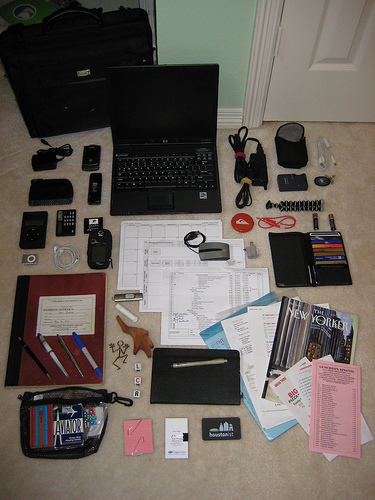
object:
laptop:
[102, 61, 223, 216]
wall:
[156, 0, 258, 131]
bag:
[0, 5, 161, 141]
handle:
[41, 4, 106, 29]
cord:
[224, 122, 269, 210]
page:
[307, 357, 361, 461]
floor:
[0, 69, 374, 499]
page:
[287, 351, 374, 450]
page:
[267, 355, 339, 463]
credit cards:
[309, 232, 341, 237]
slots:
[313, 260, 352, 286]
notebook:
[2, 271, 107, 389]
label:
[35, 292, 97, 338]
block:
[159, 265, 270, 346]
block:
[143, 239, 244, 260]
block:
[137, 223, 153, 239]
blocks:
[124, 226, 140, 239]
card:
[164, 417, 189, 460]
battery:
[86, 172, 103, 206]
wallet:
[268, 229, 354, 289]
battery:
[81, 144, 102, 173]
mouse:
[181, 229, 231, 262]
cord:
[180, 228, 209, 250]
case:
[150, 345, 246, 405]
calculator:
[55, 209, 76, 237]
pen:
[71, 329, 104, 381]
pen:
[55, 333, 87, 381]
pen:
[35, 330, 69, 379]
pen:
[14, 333, 53, 383]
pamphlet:
[260, 293, 362, 407]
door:
[261, 0, 374, 128]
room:
[0, 1, 374, 497]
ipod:
[86, 227, 114, 271]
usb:
[323, 209, 345, 234]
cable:
[35, 137, 75, 162]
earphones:
[306, 135, 337, 173]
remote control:
[87, 172, 103, 206]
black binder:
[3, 272, 32, 388]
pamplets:
[220, 295, 303, 432]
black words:
[321, 383, 329, 386]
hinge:
[271, 26, 284, 62]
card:
[122, 418, 153, 456]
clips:
[131, 436, 144, 457]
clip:
[171, 429, 192, 443]